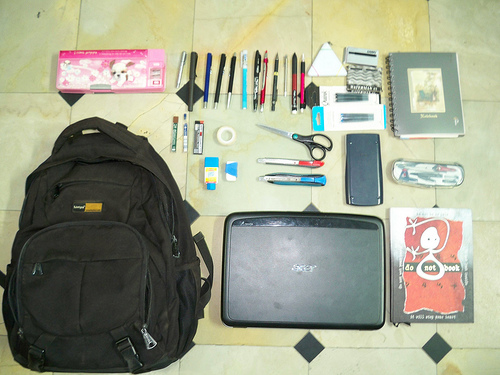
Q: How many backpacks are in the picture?
A: One.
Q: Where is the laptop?
A: Beside the backpack.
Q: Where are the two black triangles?
A: On the tlle.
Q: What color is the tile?
A: Yellow and White.